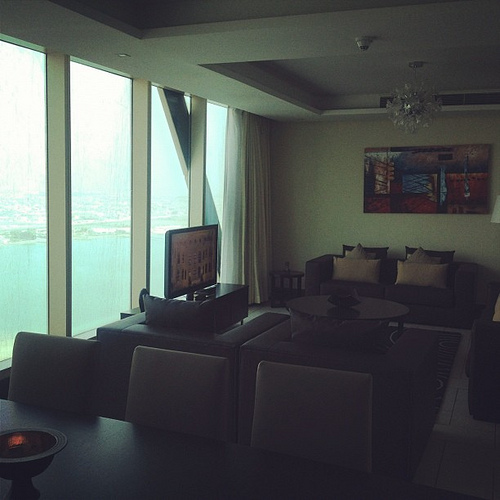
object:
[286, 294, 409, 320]
table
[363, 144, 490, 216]
picture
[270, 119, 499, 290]
wall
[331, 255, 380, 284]
pillow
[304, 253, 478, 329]
couch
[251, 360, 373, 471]
chair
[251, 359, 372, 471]
back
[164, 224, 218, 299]
screen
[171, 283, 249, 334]
table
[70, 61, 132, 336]
window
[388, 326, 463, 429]
rug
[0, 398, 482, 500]
table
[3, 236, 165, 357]
water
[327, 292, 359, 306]
bowl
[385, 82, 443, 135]
light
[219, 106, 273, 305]
curtain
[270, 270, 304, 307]
table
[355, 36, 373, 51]
camera